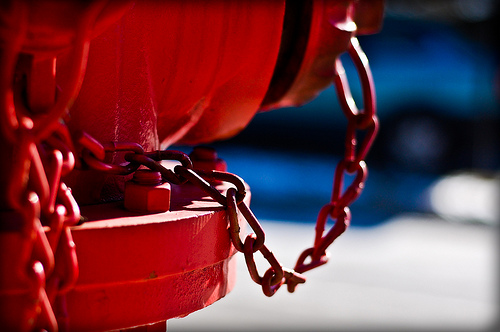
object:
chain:
[213, 181, 341, 298]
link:
[181, 163, 247, 206]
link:
[343, 115, 380, 172]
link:
[227, 189, 266, 252]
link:
[12, 123, 46, 209]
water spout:
[261, 0, 385, 110]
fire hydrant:
[5, 2, 397, 332]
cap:
[256, 4, 390, 116]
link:
[240, 244, 277, 288]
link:
[328, 157, 371, 204]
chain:
[5, 117, 81, 332]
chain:
[94, 22, 384, 301]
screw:
[192, 147, 219, 184]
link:
[332, 39, 379, 114]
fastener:
[121, 183, 175, 210]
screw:
[132, 168, 160, 213]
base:
[0, 154, 246, 330]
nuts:
[184, 145, 228, 183]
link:
[314, 203, 347, 253]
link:
[129, 150, 192, 185]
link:
[291, 246, 328, 274]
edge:
[289, 253, 309, 270]